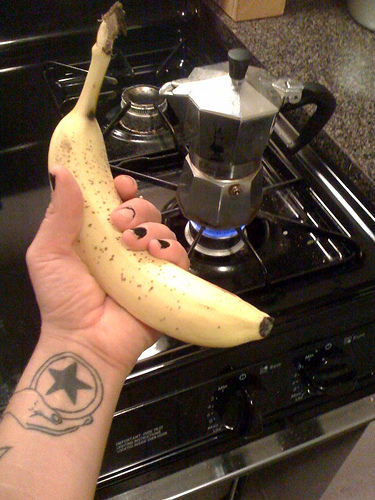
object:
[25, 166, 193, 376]
hand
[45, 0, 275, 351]
bannana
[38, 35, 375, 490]
stove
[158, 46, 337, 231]
pot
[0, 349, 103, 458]
tattoo